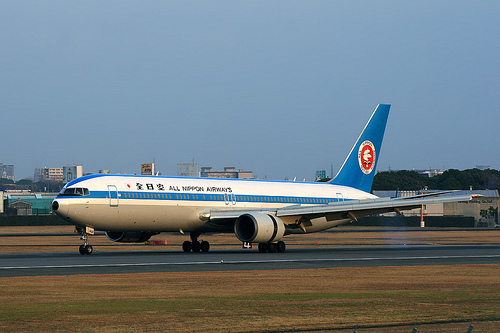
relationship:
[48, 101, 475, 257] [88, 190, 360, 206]
plane has stripe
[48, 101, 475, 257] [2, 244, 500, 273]
plane on runway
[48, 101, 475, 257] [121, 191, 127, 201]
plane has windows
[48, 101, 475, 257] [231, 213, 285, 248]
plane has engine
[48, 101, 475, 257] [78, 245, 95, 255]
plane has wheels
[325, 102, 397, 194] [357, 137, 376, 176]
tail has emblem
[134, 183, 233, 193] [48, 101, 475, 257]
name on plane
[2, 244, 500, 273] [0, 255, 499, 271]
runway has markings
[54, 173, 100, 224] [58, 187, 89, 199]
cockpit has window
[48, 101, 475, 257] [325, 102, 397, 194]
plane has tail